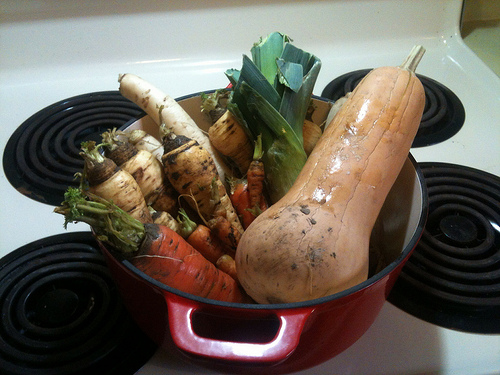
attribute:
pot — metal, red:
[62, 73, 435, 374]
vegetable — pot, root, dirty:
[47, 20, 442, 315]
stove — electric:
[9, 85, 121, 197]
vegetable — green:
[221, 26, 328, 190]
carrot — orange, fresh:
[68, 202, 237, 298]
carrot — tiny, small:
[243, 142, 265, 209]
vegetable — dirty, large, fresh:
[229, 38, 436, 313]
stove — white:
[2, 0, 500, 371]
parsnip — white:
[81, 141, 157, 204]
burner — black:
[418, 155, 500, 317]